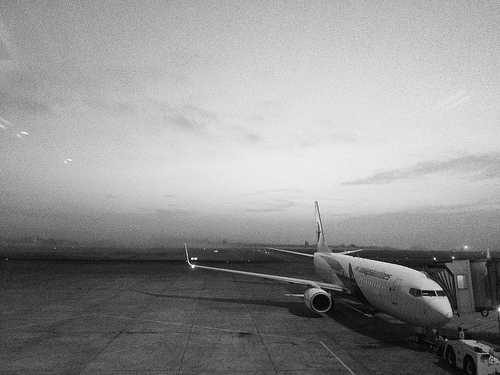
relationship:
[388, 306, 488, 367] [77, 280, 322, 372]
people on tarmac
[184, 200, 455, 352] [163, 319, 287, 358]
airplane on tarmac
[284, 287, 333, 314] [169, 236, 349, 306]
engine under wing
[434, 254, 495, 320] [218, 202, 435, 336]
ramp attached to plane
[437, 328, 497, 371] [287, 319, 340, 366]
vehicle on tarmac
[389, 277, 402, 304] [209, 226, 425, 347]
door on plane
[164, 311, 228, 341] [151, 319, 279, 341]
crack in road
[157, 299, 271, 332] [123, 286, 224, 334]
crack in road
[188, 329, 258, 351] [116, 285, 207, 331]
crack in road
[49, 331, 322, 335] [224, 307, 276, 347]
crack in road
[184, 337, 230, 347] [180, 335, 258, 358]
crack in road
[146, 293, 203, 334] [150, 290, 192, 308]
crack in road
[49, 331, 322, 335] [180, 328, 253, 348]
crack in road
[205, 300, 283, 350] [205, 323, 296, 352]
crack in road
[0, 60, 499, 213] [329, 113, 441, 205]
cloud in sky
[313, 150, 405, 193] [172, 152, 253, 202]
cloud in sky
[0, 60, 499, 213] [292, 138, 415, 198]
cloud in sky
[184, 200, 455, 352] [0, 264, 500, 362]
airplane in road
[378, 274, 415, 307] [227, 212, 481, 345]
door on airplane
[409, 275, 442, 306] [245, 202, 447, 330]
window on airplane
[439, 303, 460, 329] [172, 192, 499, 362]
nose of plane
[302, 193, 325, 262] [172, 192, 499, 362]
tail of plane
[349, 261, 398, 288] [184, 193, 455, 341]
passenger windows on plane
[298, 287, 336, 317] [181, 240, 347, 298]
engine under wing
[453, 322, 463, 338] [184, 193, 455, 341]
person in front of plane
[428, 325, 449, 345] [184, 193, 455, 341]
people in front of plane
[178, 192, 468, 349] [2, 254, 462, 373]
airplane on tarmac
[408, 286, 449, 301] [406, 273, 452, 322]
windows on cockpit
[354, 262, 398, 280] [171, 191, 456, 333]
lettering on airplane